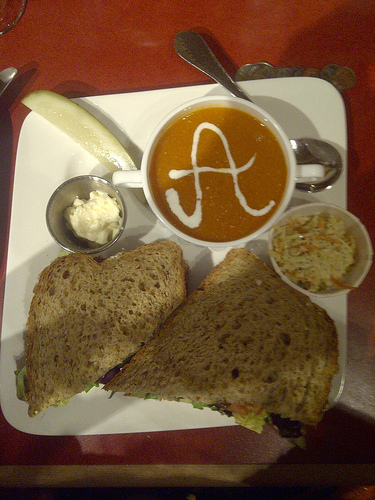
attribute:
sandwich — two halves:
[47, 247, 340, 451]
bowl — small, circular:
[265, 206, 367, 296]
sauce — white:
[164, 119, 274, 229]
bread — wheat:
[24, 238, 340, 430]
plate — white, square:
[12, 77, 350, 448]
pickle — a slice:
[19, 88, 150, 207]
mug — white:
[112, 93, 297, 248]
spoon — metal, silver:
[171, 29, 343, 192]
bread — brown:
[17, 238, 205, 422]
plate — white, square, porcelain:
[7, 94, 345, 381]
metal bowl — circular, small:
[43, 174, 127, 254]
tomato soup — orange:
[166, 116, 297, 229]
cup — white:
[103, 91, 303, 260]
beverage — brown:
[152, 106, 284, 233]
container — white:
[237, 164, 373, 312]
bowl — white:
[111, 95, 296, 248]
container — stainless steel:
[47, 173, 127, 254]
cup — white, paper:
[266, 200, 373, 296]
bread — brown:
[24, 243, 187, 417]